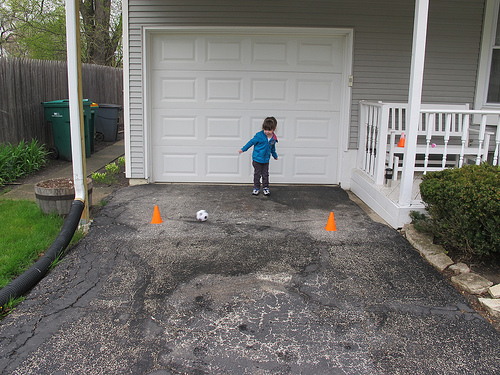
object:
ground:
[0, 183, 500, 373]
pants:
[252, 160, 271, 189]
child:
[240, 114, 280, 195]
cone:
[324, 211, 337, 231]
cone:
[150, 204, 164, 224]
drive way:
[0, 0, 87, 309]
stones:
[400, 223, 500, 317]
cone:
[398, 132, 405, 147]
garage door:
[145, 27, 348, 184]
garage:
[122, 0, 500, 186]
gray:
[133, 224, 199, 266]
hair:
[262, 116, 277, 129]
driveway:
[2, 180, 500, 375]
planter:
[34, 176, 94, 217]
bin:
[40, 98, 123, 162]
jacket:
[241, 130, 279, 164]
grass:
[0, 197, 87, 319]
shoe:
[252, 188, 261, 195]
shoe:
[262, 187, 270, 196]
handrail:
[357, 100, 500, 186]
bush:
[409, 161, 500, 256]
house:
[120, 0, 500, 230]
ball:
[195, 210, 208, 223]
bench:
[375, 100, 494, 175]